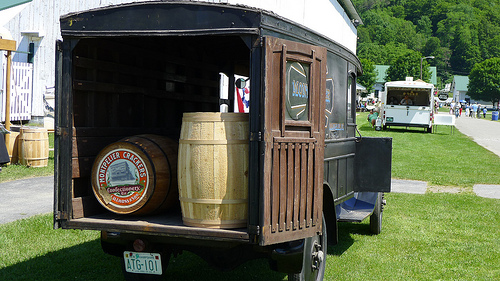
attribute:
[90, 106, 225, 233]
barrels — wooden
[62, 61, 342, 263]
paddy wagon — vintage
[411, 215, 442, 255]
grass — green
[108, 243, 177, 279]
licence plate — green, white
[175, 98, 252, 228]
barrel — upright, tan, wood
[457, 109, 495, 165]
sidewalk — paved, grey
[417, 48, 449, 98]
street lamp — metal, tall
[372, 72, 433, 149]
truck — white, parked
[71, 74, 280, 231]
door — open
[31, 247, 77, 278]
shadow — truck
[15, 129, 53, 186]
barrel — wood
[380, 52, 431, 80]
leaves — green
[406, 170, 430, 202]
stone — flat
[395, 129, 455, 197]
grass — green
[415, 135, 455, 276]
grass — green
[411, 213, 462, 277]
grass — green and visible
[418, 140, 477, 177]
grass — green and visible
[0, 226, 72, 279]
grass — green and visible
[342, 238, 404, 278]
grass — green and visible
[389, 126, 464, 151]
grass — green and visible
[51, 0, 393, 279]
car — black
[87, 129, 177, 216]
barrel — brown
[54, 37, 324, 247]
doors — car's back, open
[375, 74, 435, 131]
vehicle — white, in front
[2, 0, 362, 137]
barn — white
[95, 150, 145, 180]
lettering — white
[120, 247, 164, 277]
license plate — white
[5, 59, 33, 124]
fence — white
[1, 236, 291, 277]
shadow — of truck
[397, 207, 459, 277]
grass — green and visible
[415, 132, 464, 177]
grass — green and visible